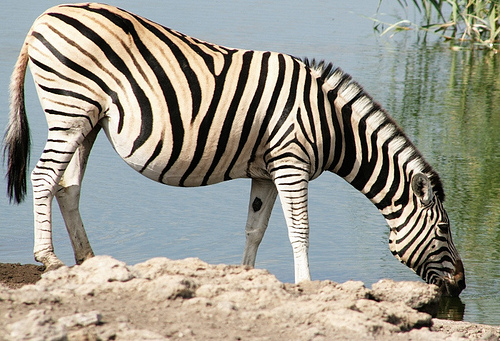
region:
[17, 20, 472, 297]
the zebra is drinking water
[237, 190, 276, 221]
the black spot is on the leg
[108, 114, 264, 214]
the belly is huge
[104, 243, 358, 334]
the ground is dry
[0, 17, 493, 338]
the scene was taken outdoors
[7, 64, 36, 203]
the tail has a black end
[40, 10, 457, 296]
the zebra has four legs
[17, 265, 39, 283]
the patch of ground is wet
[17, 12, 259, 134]
sun reflection is on the skin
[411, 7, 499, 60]
plants are growing in the water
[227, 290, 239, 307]
edge of a rock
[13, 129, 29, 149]
tail of a zebra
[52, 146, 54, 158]
back leg of a zebra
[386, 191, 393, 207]
neck of a zebra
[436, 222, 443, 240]
head of a zebra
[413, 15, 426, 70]
part of the sea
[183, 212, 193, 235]
part of the ocean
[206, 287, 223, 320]
edge of a rock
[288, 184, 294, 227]
leg of a zebra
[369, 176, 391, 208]
neck of a zebra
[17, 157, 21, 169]
tail of a zebra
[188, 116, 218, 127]
bod of a zebra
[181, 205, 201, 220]
part of the sea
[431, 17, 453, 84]
part of a water plant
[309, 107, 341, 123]
part of a zebra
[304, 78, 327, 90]
body of a zebra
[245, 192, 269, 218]
a black spot beneath a zebra's foreleg, somewhere south of its foreleg pit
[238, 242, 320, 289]
the thin fore shins of a normally weighted zebra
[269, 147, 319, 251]
foreleg's stripes become thinner & more irregular closer to the hoof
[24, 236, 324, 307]
all but one hoof hidden by the dry+crunchy ground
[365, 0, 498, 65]
small swarm of green+dried green reeds+weeds in right upper corner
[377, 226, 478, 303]
a zebra drinks. like all zebras, there's a bit of a hollow beneath its jaw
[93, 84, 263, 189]
plump abdomen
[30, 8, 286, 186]
light brownish stripes atop white stripes between black stripes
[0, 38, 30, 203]
a largely fuzzy long tail, ending in black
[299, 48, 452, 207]
this zebra's mane is brushy, bristly but trim & black+white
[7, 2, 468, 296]
the zebra is standing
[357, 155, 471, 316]
the zebra is drinking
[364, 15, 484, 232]
the water is reflecting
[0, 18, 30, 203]
the tip of the tail is black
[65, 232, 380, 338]
the dirt is tan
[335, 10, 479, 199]
the water is calm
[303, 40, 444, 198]
the mane is black and white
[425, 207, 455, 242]
the eye is open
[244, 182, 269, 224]
a black spot on the inside of the leg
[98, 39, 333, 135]
the stripes are black